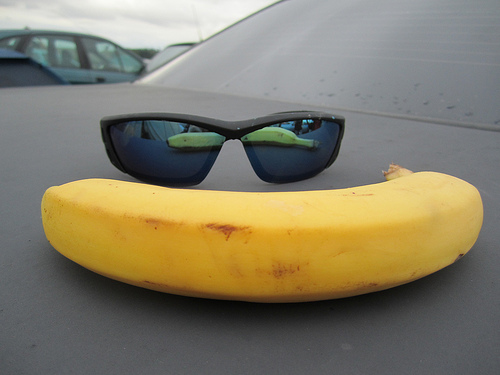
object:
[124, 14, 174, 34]
sky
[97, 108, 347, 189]
sunglasses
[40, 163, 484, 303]
banana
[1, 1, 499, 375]
car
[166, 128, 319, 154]
reflection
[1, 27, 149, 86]
car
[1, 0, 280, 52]
clouds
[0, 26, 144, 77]
windows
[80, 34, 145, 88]
door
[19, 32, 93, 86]
door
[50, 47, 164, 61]
trees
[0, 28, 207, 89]
cars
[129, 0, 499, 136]
window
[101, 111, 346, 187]
lenses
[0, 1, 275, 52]
sky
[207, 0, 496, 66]
lines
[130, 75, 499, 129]
dots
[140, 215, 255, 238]
spots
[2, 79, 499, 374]
car hood